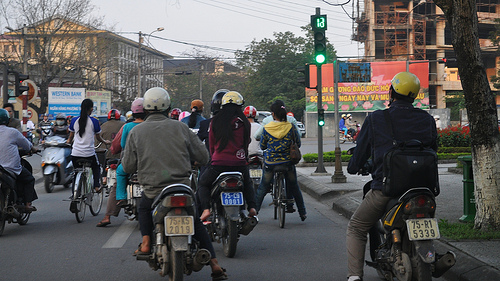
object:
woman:
[252, 105, 307, 221]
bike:
[267, 165, 294, 229]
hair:
[211, 106, 239, 152]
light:
[315, 53, 326, 63]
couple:
[198, 89, 257, 222]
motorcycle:
[205, 171, 258, 259]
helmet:
[390, 72, 421, 99]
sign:
[47, 87, 86, 121]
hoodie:
[260, 121, 302, 165]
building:
[0, 12, 175, 103]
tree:
[432, 0, 500, 235]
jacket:
[346, 102, 438, 191]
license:
[406, 218, 440, 242]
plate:
[220, 191, 243, 206]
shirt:
[67, 116, 102, 157]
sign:
[305, 60, 428, 112]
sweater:
[207, 117, 247, 166]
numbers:
[317, 18, 326, 28]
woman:
[66, 98, 102, 213]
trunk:
[437, 0, 500, 227]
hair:
[76, 98, 94, 138]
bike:
[62, 141, 104, 223]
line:
[101, 220, 136, 249]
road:
[0, 139, 449, 281]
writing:
[51, 91, 82, 96]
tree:
[0, 0, 118, 128]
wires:
[196, 1, 348, 40]